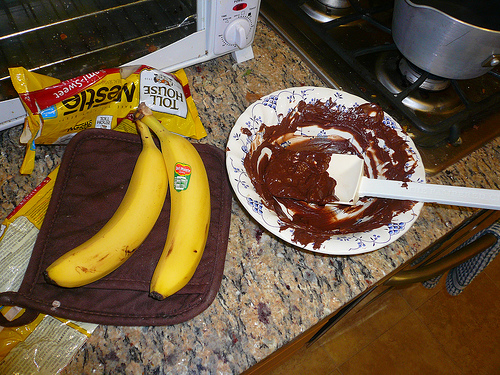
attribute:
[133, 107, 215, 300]
bananas — yellow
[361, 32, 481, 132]
burner — black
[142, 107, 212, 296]
banana — yellow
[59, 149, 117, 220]
mitt — brown oven 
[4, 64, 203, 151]
bag — plastic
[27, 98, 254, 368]
oven mitt — brown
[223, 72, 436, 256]
plate — white  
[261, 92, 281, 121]
pattern — blue stylized 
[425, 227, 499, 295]
towel — hanging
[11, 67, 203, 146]
bag — yellow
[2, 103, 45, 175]
top — torn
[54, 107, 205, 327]
bananas — yellow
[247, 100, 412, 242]
melted chocolate(frosting) — dark chocolate cake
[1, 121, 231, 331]
pot holder — brown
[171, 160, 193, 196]
banana label — red , green banana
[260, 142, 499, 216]
spatula — covered, white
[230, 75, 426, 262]
paper plate — covered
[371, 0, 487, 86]
pot — silver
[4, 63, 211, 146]
bag — yellow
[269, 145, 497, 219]
spreader — white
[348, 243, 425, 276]
countertop — marble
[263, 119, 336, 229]
icing — brown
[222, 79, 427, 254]
paper plate — paper 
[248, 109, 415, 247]
chocolate — melted  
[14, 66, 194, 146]
chips — Nestle chocolate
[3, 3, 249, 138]
oven — white microwave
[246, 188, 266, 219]
pattern — blue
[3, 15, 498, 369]
countertop — multicolored marble 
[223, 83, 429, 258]
plate — designed, white 